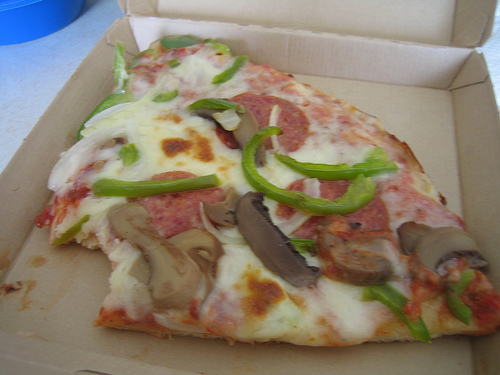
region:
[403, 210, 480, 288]
The pizza has mushrooms on it.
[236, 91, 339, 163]
A pizza with pepperoni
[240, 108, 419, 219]
The pizza has green peppers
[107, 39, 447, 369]
One slice of pizza in a box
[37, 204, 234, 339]
The slice has a bite out of it on the side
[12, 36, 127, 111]
The table is white.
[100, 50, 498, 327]
The cheese pizza has a lot of toppings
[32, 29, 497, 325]
The pizza lays in a square box.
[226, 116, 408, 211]
The peppers are green.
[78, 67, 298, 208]
The pizza has a lot of cheese.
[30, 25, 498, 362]
A slice of pizza.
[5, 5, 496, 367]
Pizza slice in the box.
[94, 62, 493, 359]
Pizza with mushrooms.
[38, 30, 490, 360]
Pizza has a bite out of it.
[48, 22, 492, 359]
Pizza has green peppers.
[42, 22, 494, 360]
Pizza has pepperoni.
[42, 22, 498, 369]
Pizza has cheese.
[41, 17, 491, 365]
Pizza slice is triangular.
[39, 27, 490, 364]
Pizza is food.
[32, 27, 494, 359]
Pizza is cooked.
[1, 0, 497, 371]
one quarter of a pizza with green peppers, mushrooms, pepperoni and onions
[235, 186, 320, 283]
sliced mushrooms on top of pizza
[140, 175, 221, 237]
pepperoni slices on pizza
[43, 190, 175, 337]
there is a bite taken out of the pizza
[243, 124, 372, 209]
a sliced green bell pepper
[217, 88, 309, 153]
another piece of sliced pepperoni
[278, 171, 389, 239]
another piece of sliced pepperoni on top of the pizza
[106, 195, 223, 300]
sliced mushroom with stem still attached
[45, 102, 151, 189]
sliced onion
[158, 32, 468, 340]
there is a supreme slice of pizza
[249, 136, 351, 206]
capsicum is green in color.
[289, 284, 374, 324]
cheese is white in color.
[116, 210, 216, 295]
mushroom is brown in color.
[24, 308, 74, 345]
box is white in color.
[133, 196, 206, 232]
pepperoni is red in color.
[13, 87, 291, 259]
picture is taken in daytime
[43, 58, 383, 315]
pizza is kept in the box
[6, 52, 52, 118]
table is white in color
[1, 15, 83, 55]
blue bowl is in the table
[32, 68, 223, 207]
pizza is in table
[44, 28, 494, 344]
Slice of pizza in box.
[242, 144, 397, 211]
Green peppers on pizza.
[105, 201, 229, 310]
Sliced mushrooms on pizza.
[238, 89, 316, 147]
Sliced pepperoni on pizza.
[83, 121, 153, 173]
Melted mozzarella cheese on pizza.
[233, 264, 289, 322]
Brown spot on melted cheese.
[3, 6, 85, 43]
Blue container sitting on table.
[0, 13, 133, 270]
Folded edge of pizza box.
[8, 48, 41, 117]
A blue table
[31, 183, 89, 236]
Red tomato sauce dripping off pizza.